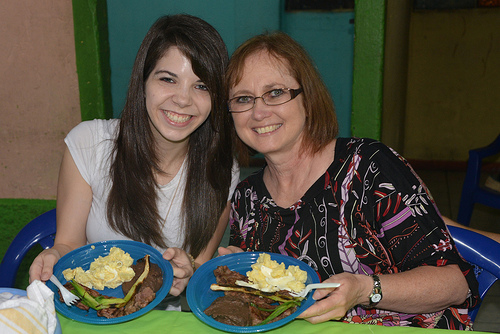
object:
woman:
[215, 32, 478, 334]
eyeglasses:
[228, 89, 308, 112]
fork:
[300, 282, 341, 296]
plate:
[186, 249, 323, 334]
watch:
[359, 276, 383, 308]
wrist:
[366, 270, 399, 309]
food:
[203, 295, 253, 325]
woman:
[24, 12, 241, 298]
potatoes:
[286, 280, 307, 293]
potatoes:
[63, 267, 76, 281]